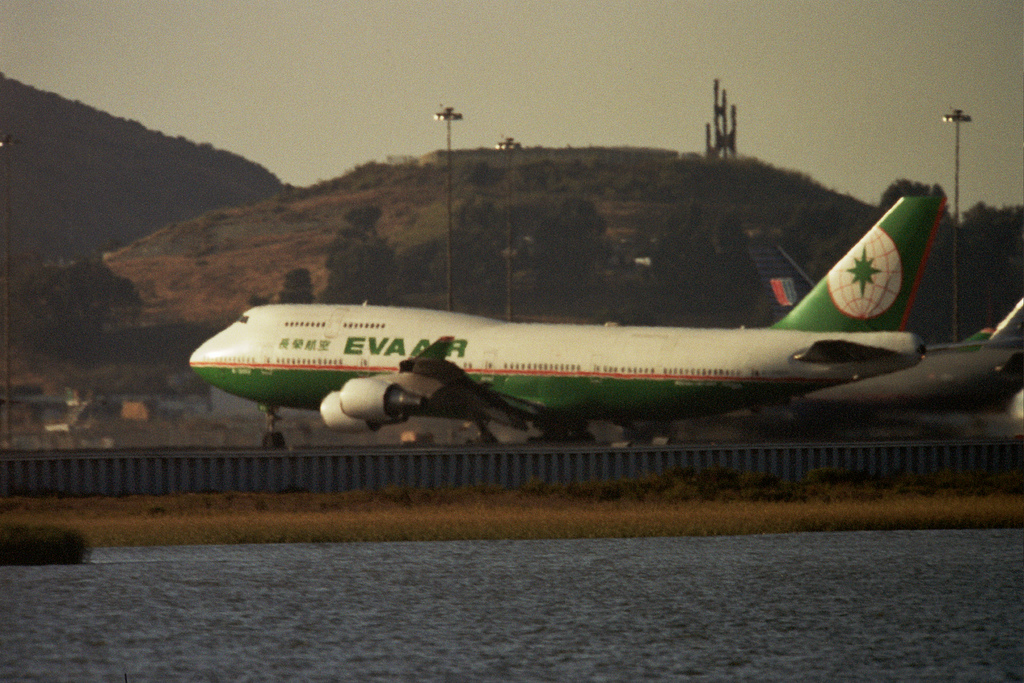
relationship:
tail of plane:
[790, 176, 950, 349] [144, 172, 960, 427]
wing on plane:
[320, 350, 495, 438] [144, 172, 960, 427]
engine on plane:
[303, 361, 439, 433] [144, 172, 960, 427]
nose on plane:
[153, 326, 253, 386] [144, 172, 960, 427]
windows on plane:
[273, 317, 765, 384] [144, 172, 960, 427]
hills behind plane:
[26, 77, 915, 304] [144, 172, 960, 427]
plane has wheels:
[144, 172, 960, 427] [254, 421, 690, 450]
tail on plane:
[790, 176, 950, 349] [144, 172, 960, 427]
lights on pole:
[434, 107, 530, 155] [422, 92, 531, 316]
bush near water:
[5, 507, 104, 562] [20, 521, 1008, 679]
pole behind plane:
[422, 92, 531, 316] [144, 172, 960, 427]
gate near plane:
[16, 434, 1012, 495] [144, 172, 960, 427]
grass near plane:
[10, 494, 1005, 534] [144, 172, 960, 427]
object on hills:
[690, 71, 777, 164] [26, 77, 915, 304]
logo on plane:
[820, 222, 911, 321] [144, 172, 960, 427]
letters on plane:
[341, 330, 482, 368] [144, 172, 960, 427]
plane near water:
[144, 172, 960, 427] [20, 521, 1008, 679]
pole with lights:
[422, 92, 531, 316] [434, 107, 530, 155]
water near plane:
[20, 521, 1008, 679] [144, 172, 960, 427]